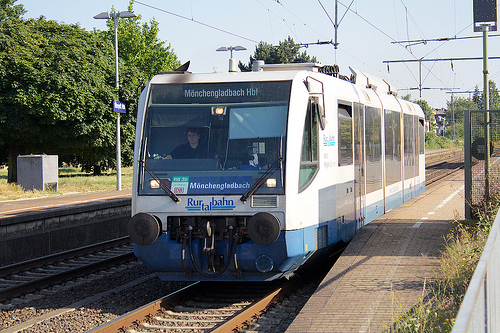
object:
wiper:
[128, 156, 210, 202]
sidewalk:
[269, 140, 500, 331]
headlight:
[146, 176, 162, 190]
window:
[144, 100, 294, 173]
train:
[121, 72, 427, 291]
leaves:
[61, 87, 66, 92]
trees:
[1, 1, 183, 172]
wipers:
[138, 158, 183, 211]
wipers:
[236, 154, 282, 198]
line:
[353, 160, 498, 332]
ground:
[280, 155, 498, 331]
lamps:
[86, 1, 141, 30]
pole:
[87, 19, 132, 193]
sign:
[96, 90, 142, 118]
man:
[159, 122, 219, 166]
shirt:
[168, 142, 210, 158]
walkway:
[287, 153, 487, 331]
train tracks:
[0, 147, 471, 328]